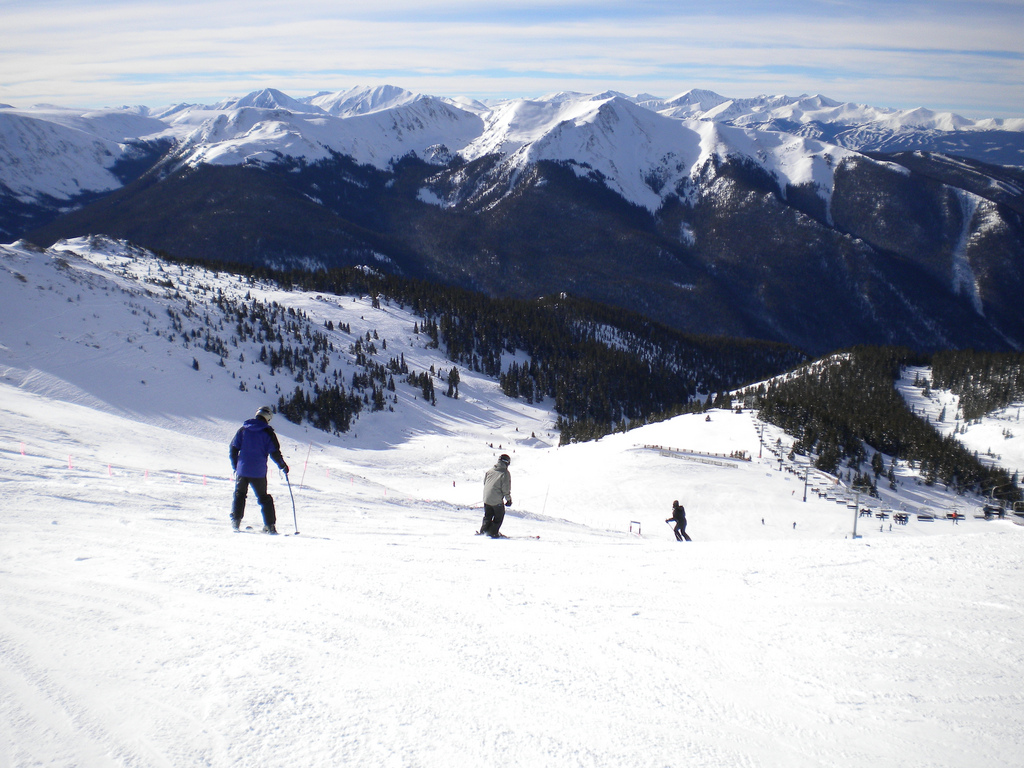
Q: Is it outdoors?
A: Yes, it is outdoors.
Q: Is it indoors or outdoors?
A: It is outdoors.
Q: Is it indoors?
A: No, it is outdoors.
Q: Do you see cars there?
A: No, there are no cars.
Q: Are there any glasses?
A: No, there are no glasses.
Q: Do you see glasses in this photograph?
A: No, there are no glasses.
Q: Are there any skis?
A: Yes, there are skis.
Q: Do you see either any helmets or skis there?
A: Yes, there are skis.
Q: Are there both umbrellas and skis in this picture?
A: No, there are skis but no umbrellas.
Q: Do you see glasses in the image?
A: No, there are no glasses.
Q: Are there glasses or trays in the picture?
A: No, there are no glasses or trays.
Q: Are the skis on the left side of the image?
A: Yes, the skis are on the left of the image.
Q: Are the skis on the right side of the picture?
A: No, the skis are on the left of the image.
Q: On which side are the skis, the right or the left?
A: The skis are on the left of the image.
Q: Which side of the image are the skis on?
A: The skis are on the left of the image.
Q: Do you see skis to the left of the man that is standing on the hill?
A: Yes, there are skis to the left of the man.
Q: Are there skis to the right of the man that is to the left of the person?
A: No, the skis are to the left of the man.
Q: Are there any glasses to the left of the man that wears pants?
A: No, there are skis to the left of the man.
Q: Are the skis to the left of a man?
A: Yes, the skis are to the left of a man.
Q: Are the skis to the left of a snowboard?
A: No, the skis are to the left of a man.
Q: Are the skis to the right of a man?
A: No, the skis are to the left of a man.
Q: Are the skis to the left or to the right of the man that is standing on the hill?
A: The skis are to the left of the man.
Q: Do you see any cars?
A: No, there are no cars.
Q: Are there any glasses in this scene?
A: No, there are no glasses.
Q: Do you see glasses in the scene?
A: No, there are no glasses.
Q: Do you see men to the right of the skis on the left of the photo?
A: Yes, there is a man to the right of the skis.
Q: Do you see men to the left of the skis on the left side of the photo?
A: No, the man is to the right of the skis.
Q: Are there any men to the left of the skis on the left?
A: No, the man is to the right of the skis.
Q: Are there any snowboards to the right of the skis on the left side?
A: No, there is a man to the right of the skis.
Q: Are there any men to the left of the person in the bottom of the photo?
A: Yes, there is a man to the left of the person.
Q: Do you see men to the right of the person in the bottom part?
A: No, the man is to the left of the person.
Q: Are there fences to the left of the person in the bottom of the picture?
A: No, there is a man to the left of the person.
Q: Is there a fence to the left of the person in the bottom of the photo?
A: No, there is a man to the left of the person.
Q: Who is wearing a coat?
A: The man is wearing a coat.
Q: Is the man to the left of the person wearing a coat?
A: Yes, the man is wearing a coat.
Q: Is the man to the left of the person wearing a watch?
A: No, the man is wearing a coat.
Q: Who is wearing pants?
A: The man is wearing pants.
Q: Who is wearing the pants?
A: The man is wearing pants.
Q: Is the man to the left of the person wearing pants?
A: Yes, the man is wearing pants.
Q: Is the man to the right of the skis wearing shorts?
A: No, the man is wearing pants.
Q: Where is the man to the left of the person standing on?
A: The man is standing on the hill.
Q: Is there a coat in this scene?
A: Yes, there is a coat.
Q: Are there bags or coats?
A: Yes, there is a coat.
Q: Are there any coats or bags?
A: Yes, there is a coat.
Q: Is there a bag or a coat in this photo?
A: Yes, there is a coat.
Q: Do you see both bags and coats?
A: No, there is a coat but no bags.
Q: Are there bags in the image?
A: No, there are no bags.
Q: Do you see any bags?
A: No, there are no bags.